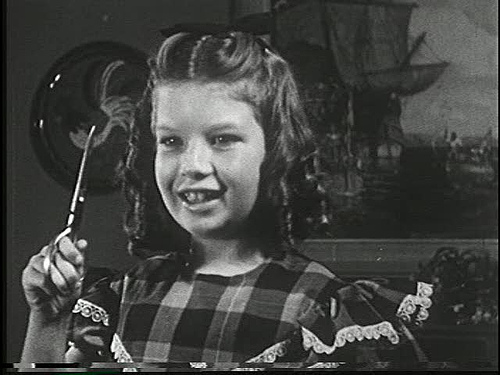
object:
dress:
[77, 236, 397, 368]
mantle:
[280, 312, 498, 367]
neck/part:
[204, 245, 251, 258]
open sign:
[128, 22, 333, 261]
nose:
[178, 142, 212, 179]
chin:
[175, 215, 233, 235]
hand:
[20, 237, 86, 321]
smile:
[176, 185, 227, 211]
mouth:
[171, 186, 222, 216]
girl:
[22, 27, 439, 374]